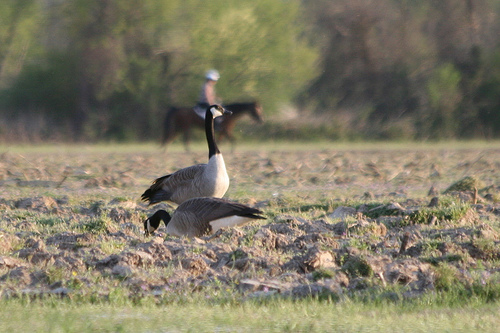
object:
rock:
[280, 246, 337, 276]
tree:
[0, 0, 130, 145]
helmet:
[202, 65, 222, 83]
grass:
[0, 138, 498, 329]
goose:
[139, 103, 268, 250]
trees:
[0, 0, 500, 142]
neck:
[203, 119, 223, 166]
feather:
[145, 170, 223, 197]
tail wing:
[225, 199, 267, 229]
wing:
[166, 208, 213, 237]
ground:
[0, 140, 500, 333]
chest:
[179, 164, 227, 196]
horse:
[157, 98, 265, 154]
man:
[198, 66, 218, 106]